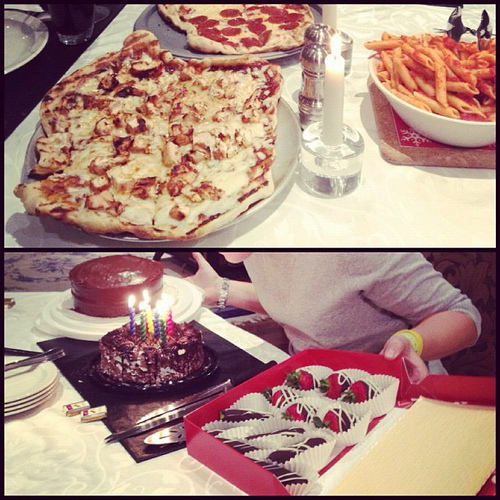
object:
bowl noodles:
[396, 59, 417, 90]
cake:
[98, 321, 205, 382]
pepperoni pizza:
[159, 3, 313, 54]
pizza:
[12, 28, 283, 240]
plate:
[131, 4, 321, 67]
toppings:
[220, 9, 241, 18]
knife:
[105, 360, 276, 441]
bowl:
[367, 56, 500, 146]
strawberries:
[345, 381, 368, 402]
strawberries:
[313, 408, 350, 432]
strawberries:
[320, 373, 349, 400]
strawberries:
[285, 370, 314, 390]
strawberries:
[264, 388, 297, 409]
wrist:
[215, 278, 234, 305]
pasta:
[443, 54, 475, 85]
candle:
[323, 58, 344, 145]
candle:
[129, 308, 135, 334]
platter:
[38, 275, 203, 341]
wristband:
[392, 329, 423, 356]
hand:
[380, 334, 427, 384]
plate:
[4, 359, 57, 403]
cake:
[68, 255, 163, 319]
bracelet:
[217, 278, 229, 308]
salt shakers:
[300, 42, 325, 131]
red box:
[187, 348, 497, 499]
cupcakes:
[268, 438, 328, 463]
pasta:
[390, 89, 433, 113]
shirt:
[244, 252, 481, 375]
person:
[179, 252, 481, 383]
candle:
[140, 313, 145, 341]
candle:
[146, 307, 153, 332]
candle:
[159, 319, 166, 341]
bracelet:
[401, 333, 418, 352]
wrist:
[398, 327, 426, 362]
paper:
[244, 435, 336, 474]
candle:
[166, 306, 176, 335]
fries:
[436, 67, 446, 101]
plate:
[22, 95, 303, 243]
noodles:
[447, 83, 479, 95]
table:
[6, 249, 499, 499]